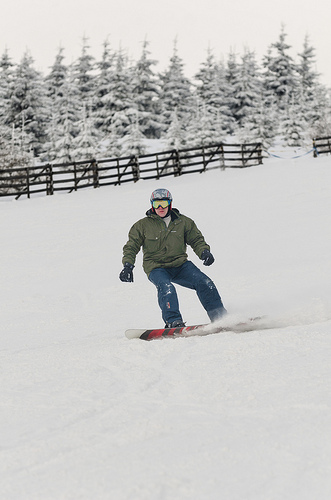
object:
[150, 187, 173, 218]
helmet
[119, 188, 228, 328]
man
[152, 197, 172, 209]
goggles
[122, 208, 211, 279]
jacket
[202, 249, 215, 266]
gloves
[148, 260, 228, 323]
pants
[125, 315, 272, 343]
snowboard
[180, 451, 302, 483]
snow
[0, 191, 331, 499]
ski slope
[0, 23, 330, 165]
trees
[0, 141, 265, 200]
fence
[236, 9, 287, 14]
sky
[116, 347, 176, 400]
track marks